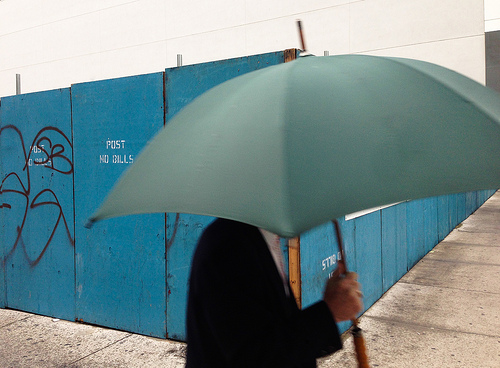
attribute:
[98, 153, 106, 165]
letter — white, stenciled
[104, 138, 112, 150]
letter — white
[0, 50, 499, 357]
wall board — blue, wooden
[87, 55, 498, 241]
umbrella — blue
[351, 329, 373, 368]
handle — wooden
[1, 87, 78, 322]
wall — blue